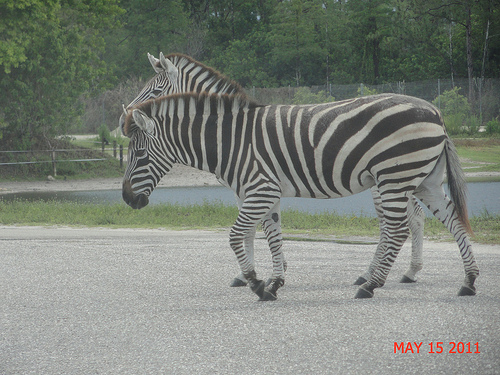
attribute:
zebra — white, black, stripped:
[122, 93, 478, 300]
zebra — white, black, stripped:
[118, 49, 478, 301]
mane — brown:
[122, 92, 260, 137]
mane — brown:
[151, 47, 246, 94]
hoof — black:
[251, 279, 266, 296]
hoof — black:
[353, 286, 374, 298]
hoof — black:
[456, 285, 475, 296]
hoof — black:
[228, 276, 247, 288]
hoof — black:
[258, 291, 277, 300]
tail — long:
[442, 130, 478, 243]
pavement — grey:
[1, 224, 499, 371]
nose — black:
[119, 181, 150, 210]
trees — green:
[0, 1, 498, 168]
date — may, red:
[392, 339, 482, 355]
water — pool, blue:
[1, 179, 498, 221]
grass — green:
[0, 197, 499, 239]